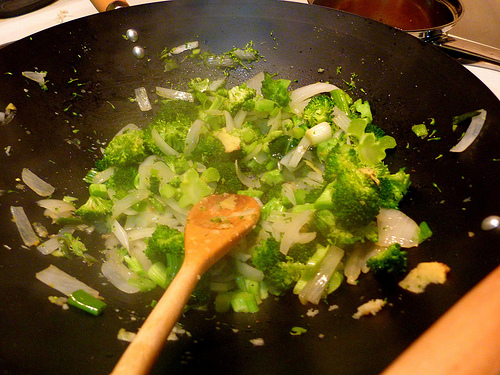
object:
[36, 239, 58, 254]
onions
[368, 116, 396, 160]
brocolli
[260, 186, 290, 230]
brocolli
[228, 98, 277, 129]
brocolli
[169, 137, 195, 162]
brocolli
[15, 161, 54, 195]
onion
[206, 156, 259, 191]
mixture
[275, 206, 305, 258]
onion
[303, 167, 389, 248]
broccoli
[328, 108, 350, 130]
onions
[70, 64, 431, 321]
food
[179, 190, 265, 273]
head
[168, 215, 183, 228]
onions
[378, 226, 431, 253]
broccoli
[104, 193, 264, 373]
spoon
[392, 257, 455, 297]
vegetable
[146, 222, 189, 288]
broccoli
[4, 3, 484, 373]
skillet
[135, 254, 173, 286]
vegetables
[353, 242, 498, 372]
table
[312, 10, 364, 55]
pan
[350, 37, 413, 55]
pan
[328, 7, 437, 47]
sauce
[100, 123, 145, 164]
broccoli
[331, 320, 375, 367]
pan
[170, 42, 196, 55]
onions